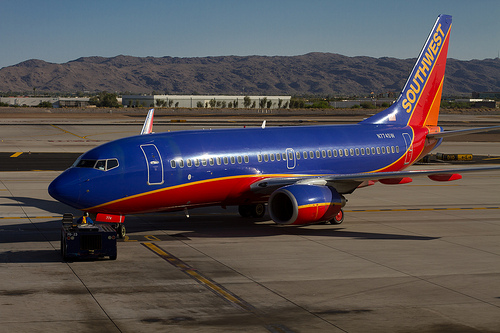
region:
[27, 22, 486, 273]
an airliner being pushed out onto the runway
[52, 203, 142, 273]
vehicle used to push a plane in reverse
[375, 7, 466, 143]
southwest logo on an airplane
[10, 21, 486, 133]
mountains in the background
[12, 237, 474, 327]
paved tarmac of the airport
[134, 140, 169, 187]
main cabin door of the plane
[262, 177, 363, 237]
large engine on wing of plane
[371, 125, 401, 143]
airplane identification/serial number in white lettering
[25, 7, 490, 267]
a southwest airlines flight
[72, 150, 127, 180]
windows to the cockpit on a plane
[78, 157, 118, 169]
The plane's cockpit windows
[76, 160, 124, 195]
The cockpit of a plane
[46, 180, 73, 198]
The nose of a plane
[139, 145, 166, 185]
A plane's front door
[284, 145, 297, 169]
A plane's emergency door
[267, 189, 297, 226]
The plane's jet engine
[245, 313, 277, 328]
Oil spill on the ground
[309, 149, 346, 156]
Passenger windows on the side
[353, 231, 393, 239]
Shadow cast by the wing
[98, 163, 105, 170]
The pilot in the cockpit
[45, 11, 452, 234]
A blue and red plane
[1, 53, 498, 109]
Mountains in the distance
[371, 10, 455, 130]
Tail of the plane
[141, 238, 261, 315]
Yellow line on the tarmac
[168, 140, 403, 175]
Windows on side of the plane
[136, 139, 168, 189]
A door on side of the plane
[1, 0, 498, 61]
A blue and clear sky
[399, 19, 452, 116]
The word "SOUTHWEST" on the tail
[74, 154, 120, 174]
Windows on front of the plane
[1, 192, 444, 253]
Plane's shadow on the tarmac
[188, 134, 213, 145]
Blue paint on plane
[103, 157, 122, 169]
Third window to the right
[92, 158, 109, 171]
Second window on right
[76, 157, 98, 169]
First window on plane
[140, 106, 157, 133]
small wing on plane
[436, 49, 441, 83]
Red stripe on wing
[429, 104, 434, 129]
Orange stripe on wing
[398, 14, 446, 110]
word southwest on wing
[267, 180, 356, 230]
Right propeller on plane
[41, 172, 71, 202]
blue nose on plane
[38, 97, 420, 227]
A red and blue plane on runway.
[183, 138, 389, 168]
The plane has windows.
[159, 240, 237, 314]
Yellow line on the pavement.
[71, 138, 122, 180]
Cockpit of the plane.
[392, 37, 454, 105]
The tail of plane says "southwest"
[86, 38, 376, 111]
Hills behind the building.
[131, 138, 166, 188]
The door of the plane.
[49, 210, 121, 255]
Person riding on the cart.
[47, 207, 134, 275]
The cart is next to the plane.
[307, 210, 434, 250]
Shadow of the wing on the pavement.